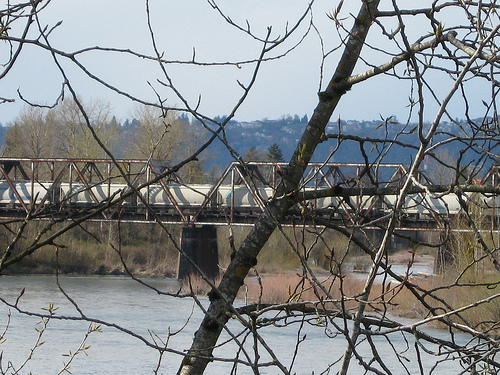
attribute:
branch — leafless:
[372, 0, 499, 20]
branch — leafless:
[346, 25, 498, 95]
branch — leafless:
[291, 178, 498, 200]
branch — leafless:
[286, 204, 499, 351]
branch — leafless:
[228, 299, 499, 369]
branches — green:
[3, 290, 115, 373]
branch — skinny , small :
[373, 167, 445, 209]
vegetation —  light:
[8, 302, 131, 374]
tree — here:
[0, 96, 197, 183]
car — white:
[0, 171, 56, 203]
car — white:
[59, 182, 131, 209]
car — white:
[134, 182, 214, 209]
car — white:
[213, 186, 304, 207]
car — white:
[384, 188, 475, 213]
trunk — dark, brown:
[173, 5, 428, 373]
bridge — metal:
[0, 156, 498, 233]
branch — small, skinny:
[68, 86, 133, 183]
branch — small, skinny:
[80, 37, 154, 69]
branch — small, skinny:
[88, 313, 155, 353]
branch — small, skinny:
[268, 22, 320, 62]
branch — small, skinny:
[111, 250, 181, 302]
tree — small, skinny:
[1, 2, 496, 371]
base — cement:
[174, 225, 219, 280]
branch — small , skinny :
[0, 285, 280, 366]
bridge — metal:
[0, 149, 496, 288]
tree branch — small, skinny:
[363, 292, 499, 338]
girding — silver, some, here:
[228, 168, 233, 223]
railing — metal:
[29, 149, 150, 216]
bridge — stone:
[57, 201, 241, 228]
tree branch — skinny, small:
[169, 0, 381, 373]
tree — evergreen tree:
[265, 140, 285, 181]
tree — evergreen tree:
[242, 142, 262, 182]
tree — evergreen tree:
[176, 139, 208, 183]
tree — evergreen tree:
[117, 97, 173, 182]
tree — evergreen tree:
[56, 90, 121, 181]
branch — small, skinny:
[143, 0, 272, 192]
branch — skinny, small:
[72, 2, 314, 65]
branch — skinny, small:
[321, 132, 475, 187]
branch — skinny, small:
[218, 300, 499, 365]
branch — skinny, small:
[1, 294, 186, 357]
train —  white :
[1, 167, 498, 224]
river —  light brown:
[0, 260, 500, 374]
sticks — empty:
[242, 296, 315, 331]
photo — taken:
[44, 137, 398, 242]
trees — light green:
[0, 100, 218, 192]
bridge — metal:
[2, 184, 489, 284]